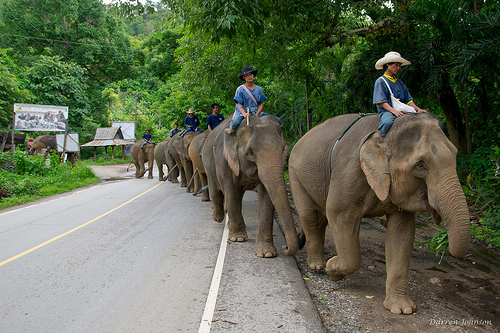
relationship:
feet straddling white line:
[223, 217, 250, 260] [185, 228, 267, 332]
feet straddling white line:
[251, 226, 284, 275] [185, 228, 267, 332]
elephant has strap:
[288, 112, 475, 312] [326, 117, 358, 184]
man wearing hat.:
[372, 52, 430, 135] [373, 44, 407, 67]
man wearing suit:
[224, 67, 284, 135] [227, 83, 269, 125]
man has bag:
[372, 51, 426, 136] [379, 77, 416, 113]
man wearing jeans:
[372, 52, 430, 135] [372, 106, 396, 136]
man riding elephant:
[372, 52, 430, 135] [288, 112, 475, 312]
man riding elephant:
[224, 67, 284, 135] [202, 113, 299, 257]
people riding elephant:
[201, 100, 225, 138] [188, 127, 215, 196]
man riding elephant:
[179, 108, 205, 138] [154, 134, 190, 182]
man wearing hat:
[373, 61, 430, 135] [376, 48, 410, 71]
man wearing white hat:
[372, 52, 430, 135] [374, 50, 413, 67]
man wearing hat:
[178, 107, 200, 140] [183, 107, 198, 117]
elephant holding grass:
[288, 112, 475, 312] [414, 210, 447, 266]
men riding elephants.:
[133, 50, 431, 160] [110, 52, 484, 294]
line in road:
[0, 180, 165, 265] [0, 159, 328, 331]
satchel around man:
[378, 75, 416, 110] [372, 51, 426, 136]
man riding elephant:
[343, 38, 425, 115] [279, 99, 484, 319]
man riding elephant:
[225, 67, 265, 135] [202, 113, 299, 257]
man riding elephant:
[183, 107, 200, 132] [170, 130, 199, 190]